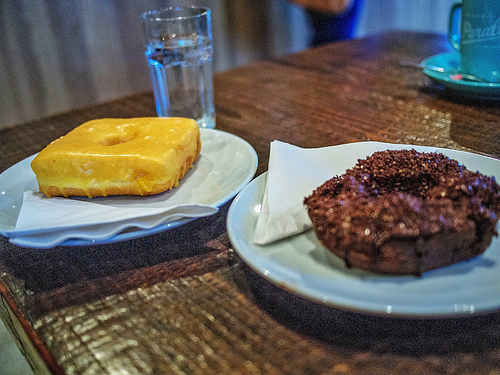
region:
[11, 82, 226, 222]
a yellow square donut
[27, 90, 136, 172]
a yellow square donut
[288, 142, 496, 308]
a chocolate flavored donut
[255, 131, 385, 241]
White napkin next to chocolate donut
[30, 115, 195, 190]
Square donut next to white napkin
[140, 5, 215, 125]
Glass of water on wooden table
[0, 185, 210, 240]
White napkin on white table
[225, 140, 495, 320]
Round white plate on wooden table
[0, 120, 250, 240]
Round white plate next to round white plate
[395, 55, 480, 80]
Utensil on white plate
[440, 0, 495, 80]
Mug on round plate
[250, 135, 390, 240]
White napkin on white plate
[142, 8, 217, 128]
Glass of water next to donut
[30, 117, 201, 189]
Square donut on top of white plate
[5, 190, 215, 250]
White napkin on top of white plate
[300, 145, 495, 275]
Chocolate donut on white plate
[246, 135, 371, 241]
White napkin on white plate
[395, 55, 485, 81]
Utensil on white plate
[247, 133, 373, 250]
White napkin next to chocolate donut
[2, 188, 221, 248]
White napkin next to donut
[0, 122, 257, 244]
White plate next to white plate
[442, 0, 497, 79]
Mug on top of plate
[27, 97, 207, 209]
this is a doughnut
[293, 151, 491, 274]
this is a doughnut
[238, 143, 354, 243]
this is a white paper towel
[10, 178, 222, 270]
this is a white paper towel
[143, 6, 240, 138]
this is a glass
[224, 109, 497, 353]
this is a plate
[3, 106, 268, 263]
this is a plate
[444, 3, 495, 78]
this is a cup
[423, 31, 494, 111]
this is a plate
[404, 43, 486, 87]
this is a tea spoon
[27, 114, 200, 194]
The creamy doughnut on the left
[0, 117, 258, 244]
A white saucer on the left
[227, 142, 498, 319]
A white saucer on the right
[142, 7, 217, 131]
An empty glass on the table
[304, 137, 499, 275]
The served brownie on the right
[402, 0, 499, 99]
A green cup on the right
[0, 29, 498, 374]
The shiny brown surface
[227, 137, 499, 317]
a plate made for dining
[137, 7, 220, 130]
a vessel made for drinking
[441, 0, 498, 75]
a vessel made for drinking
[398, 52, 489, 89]
a utensil made for dining